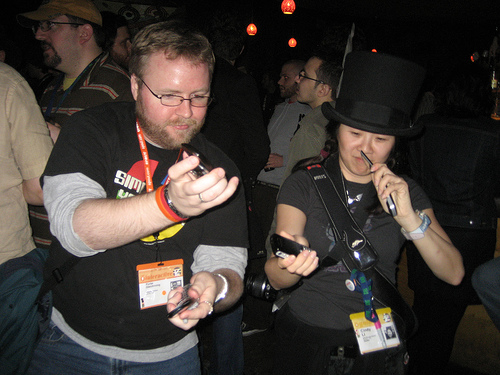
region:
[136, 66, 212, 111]
wire rimmed glasses on a man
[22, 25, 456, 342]
a young couple dressed oddly at an event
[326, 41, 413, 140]
a back top hat on a man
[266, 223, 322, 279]
a back cell phone the man is holding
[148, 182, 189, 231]
plastic and silver bracelets the man is wearing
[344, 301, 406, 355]
an identification badge the man is wearing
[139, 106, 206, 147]
the man's light brown beard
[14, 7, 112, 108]
a man in the background with a goatee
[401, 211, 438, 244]
a wrist watch a man is wearing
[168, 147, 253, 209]
a man's hand holding a cell phone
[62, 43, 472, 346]
two people holding things in their hands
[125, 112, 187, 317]
identification tag hanging from lanyard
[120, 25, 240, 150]
man wearing wire frame glasses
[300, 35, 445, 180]
woman wearing dark hat with brim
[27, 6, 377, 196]
people in background behind man and woman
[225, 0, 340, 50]
red lanterns shining light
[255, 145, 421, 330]
cross body strap over dark shirt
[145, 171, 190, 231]
metallic and colorful bands around wrist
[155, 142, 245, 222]
fingers curled around small object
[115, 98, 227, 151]
light brown mustache and beard across face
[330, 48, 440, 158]
hat is black color.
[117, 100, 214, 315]
the man is wearing orange color tag.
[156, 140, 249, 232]
the man is holding black color mobile in his right hand.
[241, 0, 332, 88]
the hanging lights are orange in color.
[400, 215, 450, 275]
the lady is wearing the watch in her left hand.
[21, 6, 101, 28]
cap is brown color.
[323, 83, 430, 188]
the lady is wearing the hat.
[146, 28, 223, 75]
hair is blonde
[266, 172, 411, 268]
lady holds mobile in both the hands.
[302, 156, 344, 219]
the lady backpack color is black.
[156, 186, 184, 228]
The bracelets on the man's wrist.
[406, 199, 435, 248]
The watch on the woman's wrist.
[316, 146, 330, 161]
The brown hair tie on the woman's braid.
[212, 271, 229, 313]
The white watch on the man's wrist.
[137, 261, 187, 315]
The man's orange and white pass on an orange chain.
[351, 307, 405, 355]
The woman's yellow and white pass hanging from her bag.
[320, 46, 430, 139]
The big black hat the woman is wearing.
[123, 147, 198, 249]
The simon design on the man's black t-shirt.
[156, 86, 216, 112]
The man's eye glasses.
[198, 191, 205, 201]
The ring on the man's finger.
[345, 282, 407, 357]
Photo Id of concert goer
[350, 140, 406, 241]
Cell Phone taking pictures at concert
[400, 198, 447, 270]
White watch on girls wrist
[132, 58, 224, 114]
Glasses on a mans face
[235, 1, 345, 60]
3 orange lights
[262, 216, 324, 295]
Voice recorder in the girls hand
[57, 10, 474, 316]
man and lady at a concert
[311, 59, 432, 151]
Black hat on ladies head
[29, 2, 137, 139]
man with striped shirt and hat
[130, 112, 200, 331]
Orange Id tag on necklace